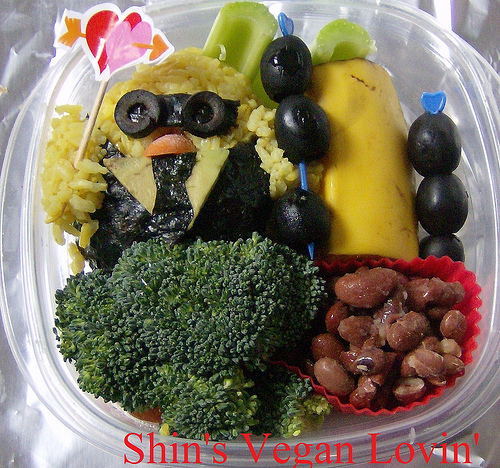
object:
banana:
[304, 59, 419, 263]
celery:
[201, 0, 280, 85]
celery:
[311, 17, 379, 66]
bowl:
[0, 0, 500, 468]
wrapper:
[271, 254, 483, 419]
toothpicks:
[420, 91, 446, 114]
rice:
[38, 45, 324, 276]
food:
[37, 0, 471, 445]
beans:
[307, 265, 469, 409]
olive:
[405, 107, 462, 178]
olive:
[413, 169, 470, 235]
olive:
[420, 232, 466, 265]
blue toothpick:
[277, 12, 315, 261]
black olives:
[258, 33, 331, 246]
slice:
[142, 134, 201, 157]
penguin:
[37, 43, 332, 268]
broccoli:
[43, 231, 329, 441]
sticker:
[51, 0, 175, 83]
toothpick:
[72, 79, 111, 172]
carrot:
[143, 133, 197, 157]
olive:
[115, 87, 162, 138]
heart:
[421, 90, 447, 116]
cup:
[270, 252, 485, 420]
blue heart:
[420, 90, 446, 115]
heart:
[81, 3, 144, 83]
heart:
[106, 20, 154, 77]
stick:
[71, 79, 108, 169]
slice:
[113, 87, 161, 138]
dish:
[0, 0, 499, 468]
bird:
[37, 46, 325, 272]